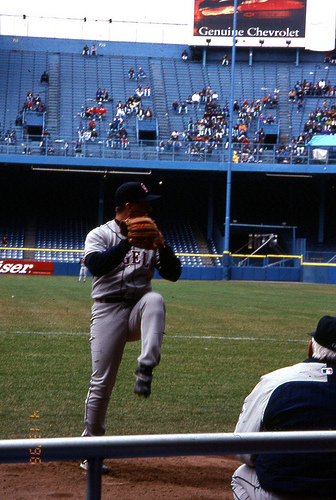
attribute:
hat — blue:
[115, 179, 154, 202]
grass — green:
[197, 342, 222, 372]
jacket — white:
[251, 386, 265, 404]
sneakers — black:
[138, 364, 154, 397]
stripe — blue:
[83, 384, 90, 408]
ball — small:
[5, 293, 20, 303]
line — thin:
[186, 331, 220, 341]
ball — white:
[8, 286, 15, 301]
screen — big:
[191, 0, 305, 34]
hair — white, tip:
[314, 348, 321, 356]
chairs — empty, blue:
[171, 226, 199, 250]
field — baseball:
[182, 274, 265, 361]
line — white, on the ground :
[212, 329, 232, 344]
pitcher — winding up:
[133, 193, 136, 204]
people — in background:
[84, 114, 233, 117]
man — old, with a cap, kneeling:
[289, 368, 293, 384]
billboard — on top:
[202, 34, 230, 36]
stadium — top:
[37, 195, 292, 212]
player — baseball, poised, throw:
[93, 342, 110, 370]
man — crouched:
[284, 367, 293, 385]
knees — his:
[236, 461, 240, 500]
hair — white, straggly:
[316, 345, 321, 357]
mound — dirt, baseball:
[90, 467, 181, 476]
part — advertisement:
[14, 249, 24, 291]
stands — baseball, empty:
[20, 197, 186, 218]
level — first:
[46, 214, 58, 268]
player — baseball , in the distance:
[102, 237, 114, 290]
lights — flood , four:
[195, 40, 301, 41]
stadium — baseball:
[40, 207, 321, 217]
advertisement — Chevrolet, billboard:
[234, 34, 279, 43]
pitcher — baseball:
[118, 234, 119, 254]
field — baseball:
[36, 285, 48, 328]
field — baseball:
[197, 296, 239, 357]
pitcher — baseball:
[117, 192, 135, 246]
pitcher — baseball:
[112, 248, 122, 272]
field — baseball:
[22, 290, 28, 331]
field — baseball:
[26, 327, 40, 422]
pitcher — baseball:
[105, 224, 124, 285]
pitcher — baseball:
[107, 223, 113, 266]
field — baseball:
[22, 268, 32, 333]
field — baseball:
[26, 314, 30, 392]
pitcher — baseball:
[108, 211, 113, 297]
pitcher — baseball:
[100, 220, 120, 290]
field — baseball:
[32, 282, 43, 400]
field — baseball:
[2, 269, 45, 421]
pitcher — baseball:
[101, 235, 110, 313]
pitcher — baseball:
[104, 220, 115, 309]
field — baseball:
[6, 274, 48, 434]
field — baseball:
[40, 295, 43, 362]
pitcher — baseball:
[93, 245, 155, 270]